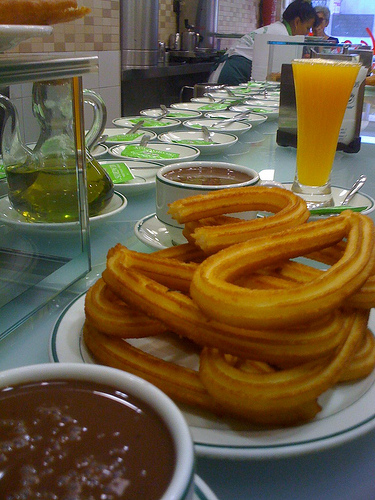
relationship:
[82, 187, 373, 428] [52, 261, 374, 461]
churros on plate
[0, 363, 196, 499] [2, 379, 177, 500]
bowl with sauce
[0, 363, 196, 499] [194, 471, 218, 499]
bowl on a saucer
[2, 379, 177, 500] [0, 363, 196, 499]
sauce in bowl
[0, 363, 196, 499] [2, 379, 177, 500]
bowl filled with sauce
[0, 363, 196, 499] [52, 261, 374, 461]
bowl next to a plate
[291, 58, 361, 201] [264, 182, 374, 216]
glass on a saucer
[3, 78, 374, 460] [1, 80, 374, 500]
plates on counter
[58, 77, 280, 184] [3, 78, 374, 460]
silverware in plates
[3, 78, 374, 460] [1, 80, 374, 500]
plates lined on counter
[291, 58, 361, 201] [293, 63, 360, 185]
glass with yellow beverage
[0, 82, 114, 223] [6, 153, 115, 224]
pitcher with oil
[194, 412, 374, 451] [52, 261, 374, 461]
trim on plate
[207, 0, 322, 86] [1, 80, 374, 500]
woman behind counter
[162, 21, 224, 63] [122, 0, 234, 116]
pots in alcove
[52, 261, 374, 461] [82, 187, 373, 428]
plate filled with churros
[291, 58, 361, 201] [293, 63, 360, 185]
glass of an orange beverage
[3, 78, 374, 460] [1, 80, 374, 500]
plates lined up on counter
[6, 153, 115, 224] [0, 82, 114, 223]
oil in pitcher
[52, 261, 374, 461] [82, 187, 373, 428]
plate of churros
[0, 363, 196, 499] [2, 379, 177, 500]
bowl containing sauce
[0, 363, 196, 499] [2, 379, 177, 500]
bowl with brown sauce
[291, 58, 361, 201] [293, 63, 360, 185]
glass containing orange beverage